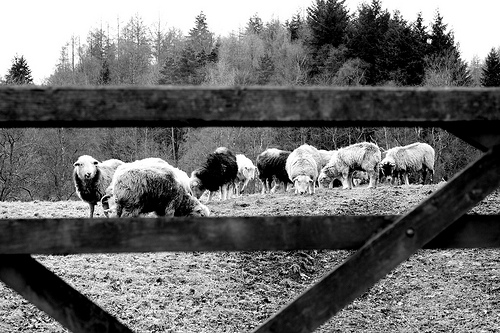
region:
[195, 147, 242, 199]
Black sheep in the pen.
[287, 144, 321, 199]
White sheep in the pen.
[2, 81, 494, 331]
Wooden fence in the forefront.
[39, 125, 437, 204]
Sheep herd in a pen.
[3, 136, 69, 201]
Brown branches in the background.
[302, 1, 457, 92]
Dark trees in the background.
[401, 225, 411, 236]
Bolt adjoining fence beams.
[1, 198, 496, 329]
Grassy ground in the pen.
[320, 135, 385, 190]
Sheep eating the grass.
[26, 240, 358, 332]
Triangle shape in the negative space.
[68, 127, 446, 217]
multi-hued squish-fluffy sheep shot through a fence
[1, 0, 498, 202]
tall trees of multiple types in the close distance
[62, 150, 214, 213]
one sheep watches, one sheep eats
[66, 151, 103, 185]
sheep who watches has expressive face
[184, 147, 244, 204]
a dark sheep, maybe with horns, eats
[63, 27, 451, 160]
trees look frothy in the fog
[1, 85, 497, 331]
a dark fence, with smudges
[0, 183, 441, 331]
feed on the ground, of unknown type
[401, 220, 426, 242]
a nail hammered into wood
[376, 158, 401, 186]
dark face, light wooliness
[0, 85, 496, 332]
A small wooden fence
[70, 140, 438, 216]
A group of grazing sheep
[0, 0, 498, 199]
A large forested area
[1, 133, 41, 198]
A small leafless tree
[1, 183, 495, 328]
A grassy field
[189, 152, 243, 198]
A sheep with dark wool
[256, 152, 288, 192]
A sheep with dark wool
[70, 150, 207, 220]
A small group of sheep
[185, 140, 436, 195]
A large group of sheep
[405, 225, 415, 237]
A rivet in the wood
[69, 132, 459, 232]
a herd of sheep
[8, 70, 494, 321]
a dark wooden gate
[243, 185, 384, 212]
hay on the ground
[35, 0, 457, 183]
a hill with trees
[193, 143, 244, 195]
a black sheep in the herd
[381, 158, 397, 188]
the face of a lamb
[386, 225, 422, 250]
a bolt on a gate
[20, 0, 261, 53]
gray sky's over the sheep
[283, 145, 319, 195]
a white woolly sheep eating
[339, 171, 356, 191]
legs of a lamb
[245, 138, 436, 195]
sheep feeding on the grass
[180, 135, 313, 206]
two black sheep and two white sheep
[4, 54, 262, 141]
a forest in the back of the fence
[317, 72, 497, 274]
old wooden dark fence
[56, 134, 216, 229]
black and white image of sheep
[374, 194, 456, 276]
an iron nail on two pieces of wood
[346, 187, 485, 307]
2 two wood beams intersecting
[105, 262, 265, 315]
grass and dirt on the grown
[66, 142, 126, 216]
sheep looking to the side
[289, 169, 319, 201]
white sheep face feeding